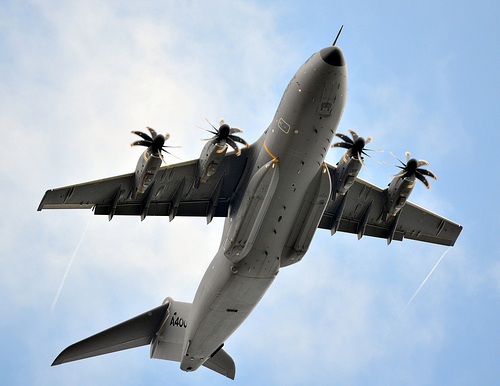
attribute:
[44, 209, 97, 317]
jetstream — white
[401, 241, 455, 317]
jetstream — white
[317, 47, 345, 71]
nose — dark, curved, black, cone-shaped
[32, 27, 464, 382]
airplane — flying, moving, gray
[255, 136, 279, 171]
strip — orange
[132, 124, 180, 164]
propeller — spinning, yellow, black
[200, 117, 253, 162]
propeller — spinning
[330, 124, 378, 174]
propeller — spinning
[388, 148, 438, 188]
propeller — spinning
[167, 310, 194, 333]
numbers — black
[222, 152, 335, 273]
stabilizers — horizontal, closed, stored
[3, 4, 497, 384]
sky — blue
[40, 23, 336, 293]
clouds — high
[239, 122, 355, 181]
highlights — orange